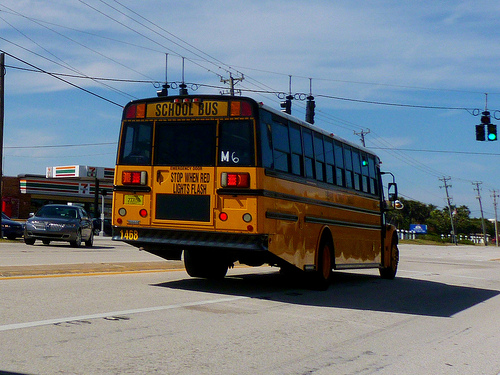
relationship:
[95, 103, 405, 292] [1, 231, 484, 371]
bus in street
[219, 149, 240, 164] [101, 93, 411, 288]
m6 on bus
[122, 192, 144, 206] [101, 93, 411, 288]
license plate on bus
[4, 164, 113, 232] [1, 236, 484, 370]
building on road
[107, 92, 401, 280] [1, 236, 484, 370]
bus on road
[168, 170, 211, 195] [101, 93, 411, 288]
writing on bus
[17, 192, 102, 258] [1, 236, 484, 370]
car on road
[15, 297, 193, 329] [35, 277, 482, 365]
white line on road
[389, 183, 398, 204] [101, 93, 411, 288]
mirror on bus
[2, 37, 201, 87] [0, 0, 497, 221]
clouds in sky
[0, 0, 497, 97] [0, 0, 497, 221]
white clouds in sky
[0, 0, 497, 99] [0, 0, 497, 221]
clouds in sky